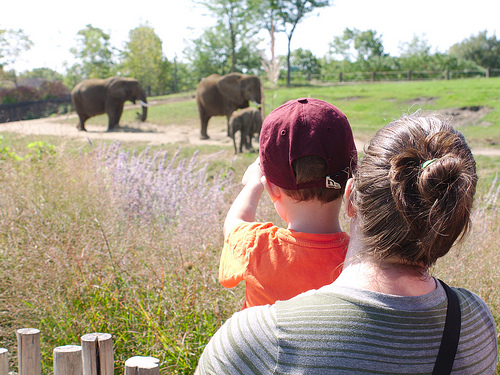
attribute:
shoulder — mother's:
[419, 277, 484, 335]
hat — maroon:
[251, 90, 365, 194]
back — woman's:
[256, 273, 473, 371]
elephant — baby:
[214, 95, 270, 159]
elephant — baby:
[225, 101, 265, 154]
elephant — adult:
[197, 69, 263, 139]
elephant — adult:
[70, 76, 147, 136]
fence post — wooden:
[79, 329, 116, 372]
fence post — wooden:
[15, 324, 40, 373]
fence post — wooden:
[52, 339, 81, 372]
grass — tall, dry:
[0, 138, 499, 355]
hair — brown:
[355, 116, 478, 266]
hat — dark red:
[256, 97, 360, 190]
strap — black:
[430, 276, 460, 373]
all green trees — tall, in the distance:
[207, 2, 309, 86]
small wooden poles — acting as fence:
[14, 322, 164, 373]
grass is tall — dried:
[119, 154, 227, 256]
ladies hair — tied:
[359, 105, 489, 273]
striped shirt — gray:
[196, 287, 499, 374]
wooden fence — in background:
[2, 81, 75, 127]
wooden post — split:
[79, 326, 119, 371]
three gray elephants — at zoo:
[57, 60, 267, 154]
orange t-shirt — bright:
[222, 184, 352, 302]